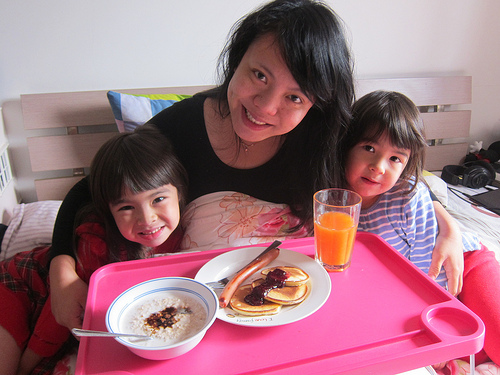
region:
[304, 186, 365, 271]
a glass of orange juice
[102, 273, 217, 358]
a blue and white bowl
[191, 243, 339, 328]
a white plate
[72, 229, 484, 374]
a large pink plate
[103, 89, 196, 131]
part of a pillow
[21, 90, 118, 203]
part of a wooden bench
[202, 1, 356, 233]
part of a woman's long black hair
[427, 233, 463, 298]
the hand of a woman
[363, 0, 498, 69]
part of a painted white wall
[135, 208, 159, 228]
the nose of a girl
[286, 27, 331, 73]
bang on womans forehead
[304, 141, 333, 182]
woman with long hair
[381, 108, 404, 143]
bang on little girl forehead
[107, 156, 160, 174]
girls hair is black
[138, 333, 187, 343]
oatmeal in round bowl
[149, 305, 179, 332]
topping on top oatmeal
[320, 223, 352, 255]
orange juice in glass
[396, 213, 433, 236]
girl wearing plaid shirt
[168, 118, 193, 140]
woman wearing black shirt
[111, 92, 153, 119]
pillow behind womans back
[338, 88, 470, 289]
Girl wearing a striped shirt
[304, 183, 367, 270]
Glass on the tray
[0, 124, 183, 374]
Girl wearing a red shirt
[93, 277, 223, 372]
Bowl on the tray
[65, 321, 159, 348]
Spoon in the bowl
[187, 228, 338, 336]
Plate on the tray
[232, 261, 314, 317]
Pancakes on the plate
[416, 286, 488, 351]
Cup holder on the tray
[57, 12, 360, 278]
Woman wearing a black shirt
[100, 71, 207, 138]
Pillow behind the woman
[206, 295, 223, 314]
the bowl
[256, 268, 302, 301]
pancakes on the plate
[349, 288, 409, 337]
a pink tray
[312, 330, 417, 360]
a tray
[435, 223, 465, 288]
the womens hand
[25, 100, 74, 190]
the headboard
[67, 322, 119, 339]
handle of a untensil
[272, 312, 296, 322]
the plate is white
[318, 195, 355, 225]
the glass has liquid in it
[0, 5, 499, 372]
a group of people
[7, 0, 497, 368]
a scene inside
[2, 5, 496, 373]
a scene during the day time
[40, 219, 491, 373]
a tray of breakfast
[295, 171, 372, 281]
a glass of orange juice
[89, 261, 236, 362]
a bowl of oatmeal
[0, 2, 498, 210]
a white wall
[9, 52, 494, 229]
a backboard of a bed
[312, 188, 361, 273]
a glass of orange juice on a tray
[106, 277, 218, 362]
a bowl of oatmeal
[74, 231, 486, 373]
a pink bed tray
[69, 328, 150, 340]
a spoon in a bowl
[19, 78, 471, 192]
a slatted wooden hadboard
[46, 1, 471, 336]
a woman in bed with two children